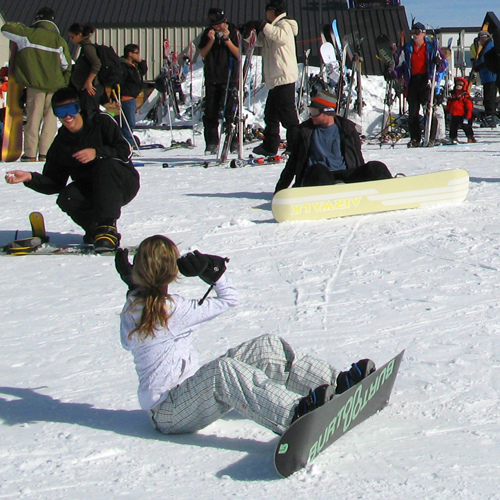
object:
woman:
[114, 233, 372, 473]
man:
[3, 85, 138, 251]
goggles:
[55, 103, 79, 120]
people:
[4, 86, 142, 252]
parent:
[381, 22, 445, 145]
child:
[441, 76, 479, 146]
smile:
[63, 118, 75, 124]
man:
[0, 8, 72, 164]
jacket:
[0, 18, 72, 92]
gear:
[22, 102, 143, 230]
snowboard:
[274, 349, 403, 476]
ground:
[0, 122, 495, 498]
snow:
[0, 56, 497, 500]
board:
[274, 351, 404, 477]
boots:
[92, 227, 122, 253]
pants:
[147, 331, 342, 430]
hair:
[116, 235, 188, 343]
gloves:
[176, 247, 227, 283]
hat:
[37, 6, 57, 27]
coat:
[444, 74, 473, 120]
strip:
[0, 28, 68, 75]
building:
[0, 1, 406, 83]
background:
[0, 0, 499, 492]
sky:
[399, 0, 495, 20]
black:
[90, 172, 111, 203]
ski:
[332, 19, 346, 60]